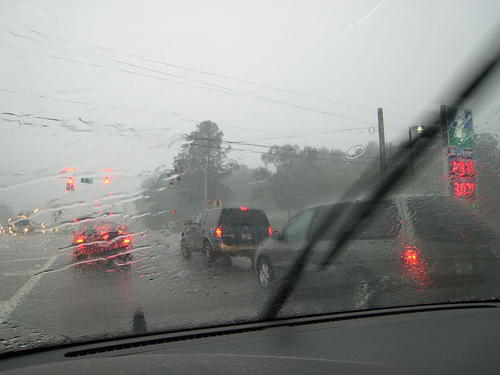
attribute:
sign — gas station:
[444, 112, 479, 157]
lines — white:
[0, 251, 62, 326]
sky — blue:
[4, 2, 494, 190]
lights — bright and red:
[72, 231, 129, 251]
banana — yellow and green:
[447, 98, 498, 178]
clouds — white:
[317, 40, 405, 109]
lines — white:
[17, 247, 60, 299]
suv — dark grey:
[254, 195, 497, 305]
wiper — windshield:
[253, 62, 486, 312]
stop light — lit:
[99, 172, 112, 187]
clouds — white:
[77, 57, 210, 132]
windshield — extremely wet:
[175, 83, 426, 278]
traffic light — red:
[62, 177, 77, 187]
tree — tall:
[173, 117, 235, 227]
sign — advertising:
[442, 106, 474, 194]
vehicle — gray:
[259, 207, 489, 290]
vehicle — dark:
[178, 200, 274, 272]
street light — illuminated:
[409, 122, 424, 134]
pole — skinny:
[372, 102, 392, 203]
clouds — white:
[177, 23, 277, 77]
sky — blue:
[4, 2, 496, 104]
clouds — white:
[131, 50, 211, 110]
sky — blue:
[347, 100, 394, 115]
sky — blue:
[60, 59, 117, 114]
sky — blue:
[84, 50, 125, 99]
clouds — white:
[68, 54, 110, 119]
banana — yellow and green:
[159, 199, 425, 283]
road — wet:
[2, 231, 351, 354]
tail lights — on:
[75, 232, 139, 249]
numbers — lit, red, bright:
[449, 154, 475, 204]